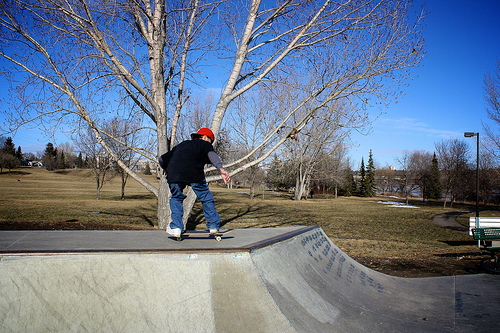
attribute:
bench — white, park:
[458, 211, 492, 249]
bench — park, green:
[452, 221, 498, 269]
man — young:
[134, 109, 217, 230]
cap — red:
[177, 113, 217, 142]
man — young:
[161, 121, 232, 238]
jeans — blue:
[153, 168, 229, 247]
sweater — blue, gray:
[151, 136, 221, 186]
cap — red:
[189, 123, 215, 140]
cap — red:
[190, 128, 216, 142]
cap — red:
[185, 125, 219, 142]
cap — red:
[190, 125, 220, 141]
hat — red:
[191, 125, 217, 138]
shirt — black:
[158, 139, 228, 191]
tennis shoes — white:
[163, 222, 223, 240]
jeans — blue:
[162, 182, 217, 232]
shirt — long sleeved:
[152, 138, 235, 193]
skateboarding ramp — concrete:
[24, 230, 490, 322]